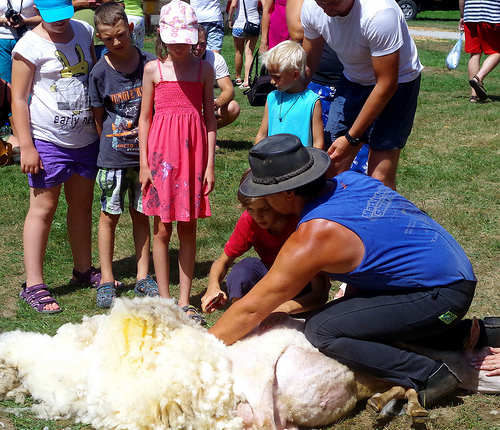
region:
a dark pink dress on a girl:
[132, 53, 217, 229]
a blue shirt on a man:
[299, 167, 481, 295]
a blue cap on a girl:
[31, 0, 73, 21]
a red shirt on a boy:
[220, 205, 290, 270]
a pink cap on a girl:
[151, 0, 206, 50]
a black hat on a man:
[236, 132, 332, 201]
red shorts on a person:
[457, 17, 497, 55]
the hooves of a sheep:
[363, 380, 439, 427]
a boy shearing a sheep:
[198, 171, 329, 331]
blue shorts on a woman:
[229, 26, 248, 39]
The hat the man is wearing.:
[239, 135, 329, 195]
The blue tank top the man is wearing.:
[313, 187, 468, 287]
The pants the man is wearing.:
[312, 285, 471, 380]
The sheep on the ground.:
[4, 320, 375, 428]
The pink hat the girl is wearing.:
[159, 4, 200, 46]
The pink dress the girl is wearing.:
[142, 60, 207, 222]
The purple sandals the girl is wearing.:
[19, 271, 117, 307]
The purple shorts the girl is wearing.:
[35, 141, 96, 178]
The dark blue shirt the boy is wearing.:
[88, 54, 148, 163]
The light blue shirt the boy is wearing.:
[256, 94, 317, 144]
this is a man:
[228, 143, 464, 367]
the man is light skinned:
[261, 271, 305, 296]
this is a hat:
[243, 137, 315, 184]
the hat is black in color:
[256, 140, 296, 188]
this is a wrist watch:
[345, 133, 365, 140]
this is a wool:
[109, 323, 184, 414]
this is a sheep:
[266, 340, 331, 410]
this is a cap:
[37, 1, 82, 22]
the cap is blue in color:
[44, 4, 70, 14]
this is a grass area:
[431, 110, 498, 185]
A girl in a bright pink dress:
[139, 0, 220, 315]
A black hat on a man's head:
[228, 130, 336, 195]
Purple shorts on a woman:
[21, 135, 106, 185]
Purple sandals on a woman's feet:
[19, 264, 124, 319]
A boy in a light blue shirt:
[248, 41, 325, 151]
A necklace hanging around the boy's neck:
[274, 80, 305, 122]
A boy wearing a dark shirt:
[80, 0, 162, 310]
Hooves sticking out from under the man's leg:
[369, 380, 430, 426]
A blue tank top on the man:
[288, 169, 483, 294]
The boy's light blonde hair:
[261, 40, 310, 77]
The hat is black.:
[238, 132, 328, 192]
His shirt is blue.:
[311, 175, 470, 296]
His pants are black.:
[290, 293, 482, 395]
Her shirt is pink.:
[149, 88, 214, 223]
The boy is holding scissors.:
[192, 288, 229, 320]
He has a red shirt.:
[219, 212, 277, 273]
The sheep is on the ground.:
[8, 290, 425, 427]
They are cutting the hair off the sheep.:
[25, 188, 431, 428]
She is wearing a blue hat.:
[25, 1, 84, 27]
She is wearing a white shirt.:
[14, 35, 100, 147]